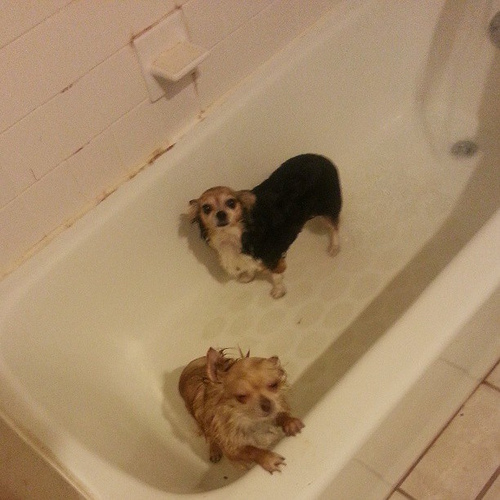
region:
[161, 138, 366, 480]
Two dogs inside the bathtub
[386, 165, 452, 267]
White color bathtub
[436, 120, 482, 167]
Outlet of the bathtub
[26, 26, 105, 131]
white color wall tiles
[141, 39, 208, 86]
Soap stand near the bathtub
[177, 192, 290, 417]
Dogs looking at the camera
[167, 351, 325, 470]
Brown color dog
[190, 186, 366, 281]
Brown and black color dog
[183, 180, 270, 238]
Head of the dog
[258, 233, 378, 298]
Legs of the dog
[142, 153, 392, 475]
two dogs in white bathtub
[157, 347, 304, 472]
dog trying to climb out of bathtub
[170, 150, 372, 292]
black and tan dog standing in white bathtub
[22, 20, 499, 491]
white bathtub with two dogs in it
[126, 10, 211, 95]
white soap holder attached to wall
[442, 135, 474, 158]
silver drain of white bathtub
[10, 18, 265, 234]
discolored grout on wall behind bathtub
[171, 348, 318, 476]
wet tan dog in bathtub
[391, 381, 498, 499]
tiles in front of white bathtub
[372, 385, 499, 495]
dark grout between tiles of floor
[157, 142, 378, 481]
two dogs in a bathtub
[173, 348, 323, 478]
dog standing on its hind legs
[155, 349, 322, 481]
fluffy long haired dog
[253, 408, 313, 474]
frong paws on the edge of the tub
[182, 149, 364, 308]
brown, white, and black dog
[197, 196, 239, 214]
two small black eyes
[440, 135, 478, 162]
silver drain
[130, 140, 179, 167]
brown line on the edge of the tub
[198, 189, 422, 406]
circles on the floor of the tub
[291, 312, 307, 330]
black spot on the floor of the tub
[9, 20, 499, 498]
two dogs in a bathtub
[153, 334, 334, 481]
a brown dog is wet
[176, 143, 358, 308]
a dog is looking up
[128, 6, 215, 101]
a soapdish on a wall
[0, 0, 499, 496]
bathtub is white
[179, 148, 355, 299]
dog is color brown and black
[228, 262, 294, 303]
front legs of dog are brown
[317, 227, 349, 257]
a brown back leg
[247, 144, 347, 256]
body of dog is black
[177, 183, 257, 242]
head of dog is brown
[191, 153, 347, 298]
small water soaked dog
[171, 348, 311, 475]
small water soaked dog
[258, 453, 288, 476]
small wet dog paw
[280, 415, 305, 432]
small wet dog paw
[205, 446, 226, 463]
small wet dog paw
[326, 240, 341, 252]
small wet dog paw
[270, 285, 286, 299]
small wet dog paw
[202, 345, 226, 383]
small wet dog ear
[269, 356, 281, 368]
small wet dog ear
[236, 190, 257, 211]
small wet dog ear